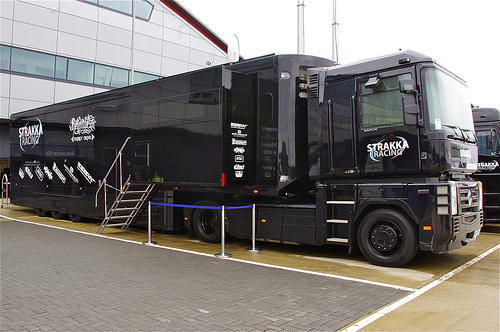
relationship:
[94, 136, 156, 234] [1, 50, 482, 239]
stairs leading into camper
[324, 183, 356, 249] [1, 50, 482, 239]
steps leading into camper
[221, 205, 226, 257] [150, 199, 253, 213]
pole with blue barrier rope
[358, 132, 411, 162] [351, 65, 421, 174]
logo on door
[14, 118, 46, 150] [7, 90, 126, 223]
logo on backend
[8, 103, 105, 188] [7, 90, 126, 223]
sponsors on backend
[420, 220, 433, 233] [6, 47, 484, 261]
light on truck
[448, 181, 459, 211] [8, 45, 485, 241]
headlight on truck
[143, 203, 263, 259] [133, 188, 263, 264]
rods on barricade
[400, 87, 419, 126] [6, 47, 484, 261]
side-view mirror on truck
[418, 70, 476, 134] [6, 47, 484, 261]
windshield on truck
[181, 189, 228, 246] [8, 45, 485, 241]
side wheel on truck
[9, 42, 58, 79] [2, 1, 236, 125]
window on building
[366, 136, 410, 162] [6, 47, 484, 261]
letter on truck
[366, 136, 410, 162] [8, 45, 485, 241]
letter on truck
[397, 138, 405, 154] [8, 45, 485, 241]
letter on truck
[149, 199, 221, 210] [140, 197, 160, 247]
cord between pole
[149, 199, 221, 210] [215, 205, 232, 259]
cord between pole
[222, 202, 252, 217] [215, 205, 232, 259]
cord between pole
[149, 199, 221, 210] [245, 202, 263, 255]
cord between pole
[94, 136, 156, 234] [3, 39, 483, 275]
stairs to truck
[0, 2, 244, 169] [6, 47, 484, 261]
building behind truck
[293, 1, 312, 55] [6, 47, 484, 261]
pole behind truck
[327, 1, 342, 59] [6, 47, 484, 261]
pole behind truck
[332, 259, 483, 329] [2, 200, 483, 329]
line on lot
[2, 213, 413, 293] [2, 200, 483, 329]
line on lot